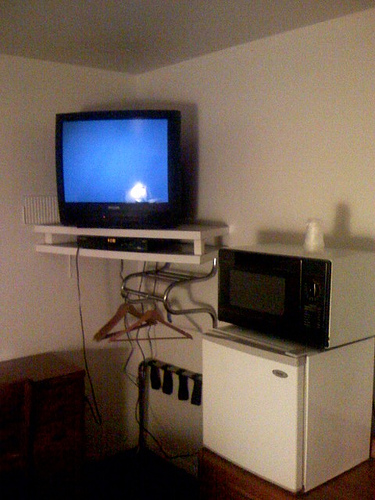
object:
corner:
[191, 230, 206, 244]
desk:
[0, 351, 88, 499]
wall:
[0, 55, 135, 474]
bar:
[123, 284, 165, 303]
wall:
[135, 3, 374, 469]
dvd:
[76, 237, 163, 251]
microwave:
[213, 245, 374, 351]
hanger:
[105, 294, 195, 347]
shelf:
[35, 243, 227, 265]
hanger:
[91, 286, 157, 342]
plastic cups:
[299, 215, 325, 253]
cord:
[75, 243, 105, 450]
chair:
[0, 367, 87, 499]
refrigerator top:
[201, 325, 374, 380]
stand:
[33, 225, 228, 266]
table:
[195, 447, 374, 499]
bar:
[136, 356, 204, 451]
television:
[53, 111, 186, 231]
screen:
[63, 119, 170, 203]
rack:
[144, 272, 175, 284]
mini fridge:
[199, 322, 374, 496]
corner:
[359, 446, 375, 475]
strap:
[186, 372, 204, 406]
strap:
[176, 367, 189, 402]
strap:
[158, 361, 175, 396]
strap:
[147, 356, 162, 391]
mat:
[0, 445, 202, 500]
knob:
[308, 281, 319, 299]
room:
[0, 1, 374, 499]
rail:
[119, 265, 217, 335]